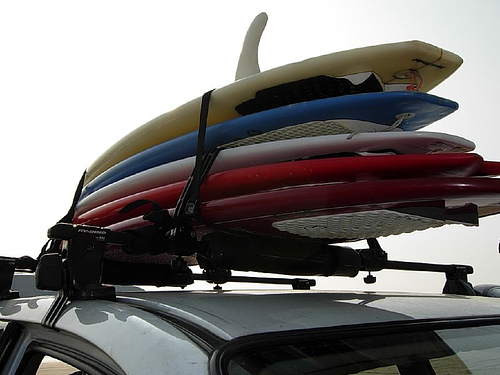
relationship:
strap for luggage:
[145, 90, 222, 172] [113, 139, 309, 305]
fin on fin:
[234, 19, 310, 76] [235, 11, 273, 81]